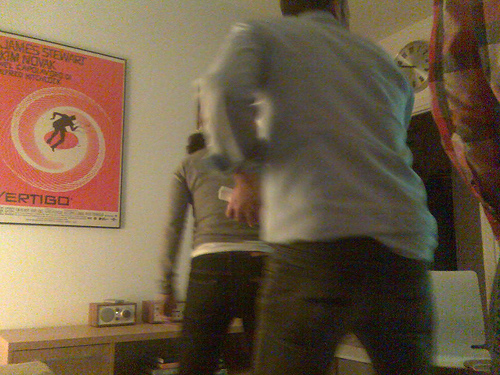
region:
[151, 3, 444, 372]
Two people standing facing away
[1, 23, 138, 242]
Picture hanging on a wall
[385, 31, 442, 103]
clock hanging on the wall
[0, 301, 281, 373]
Table pushed against the wall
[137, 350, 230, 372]
Many books on a shelf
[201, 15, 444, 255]
Man wearing a grey shirt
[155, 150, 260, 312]
man wearing a grey shirt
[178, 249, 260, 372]
Man wearing jean pants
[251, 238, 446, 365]
man wearing jean pants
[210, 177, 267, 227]
controller in man's hand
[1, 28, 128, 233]
Red, black and white wall sign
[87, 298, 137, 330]
Speaker sitting on desk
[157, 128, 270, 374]
Man with grey sweater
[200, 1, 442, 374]
Man in a grey sweater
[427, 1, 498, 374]
Person wearing plaid shirt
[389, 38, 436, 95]
Silver wall clock on wall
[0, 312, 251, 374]
Wooden desk against wall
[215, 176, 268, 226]
White wii remote being held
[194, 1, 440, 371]
Man holding Wii remote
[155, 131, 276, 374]
Man standing on floor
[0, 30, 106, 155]
Poster saying James stewart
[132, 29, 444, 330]
Two men in motion blurr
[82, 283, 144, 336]
Old style radio light on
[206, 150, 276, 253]
Paper in mans hand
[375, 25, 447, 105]
Silver clock with roman numerals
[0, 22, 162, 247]
Poster with Vertigo on the front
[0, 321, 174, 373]
wooden desk with idem on top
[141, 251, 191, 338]
arm in motion blurr on radio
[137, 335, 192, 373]
Books stacked on top of eachother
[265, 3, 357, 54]
man looking to his right in sweater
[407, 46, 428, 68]
this is a wall clock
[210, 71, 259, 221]
this is a hand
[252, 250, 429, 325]
this are the buttocks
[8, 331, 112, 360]
this is a stand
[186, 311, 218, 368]
this is the thigh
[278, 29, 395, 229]
this is the back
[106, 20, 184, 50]
this is the wall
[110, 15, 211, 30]
the wall is white in colour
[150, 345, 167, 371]
these are the books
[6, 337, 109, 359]
the stand is brown in colour